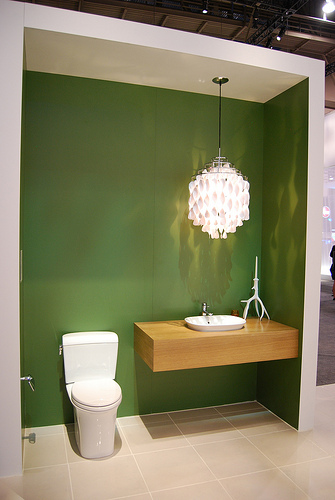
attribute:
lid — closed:
[71, 378, 121, 406]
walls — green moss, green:
[19, 69, 308, 428]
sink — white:
[179, 315, 248, 332]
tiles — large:
[165, 413, 310, 486]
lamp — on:
[186, 75, 261, 253]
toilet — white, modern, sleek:
[56, 330, 123, 456]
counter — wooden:
[140, 329, 287, 371]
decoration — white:
[239, 255, 274, 322]